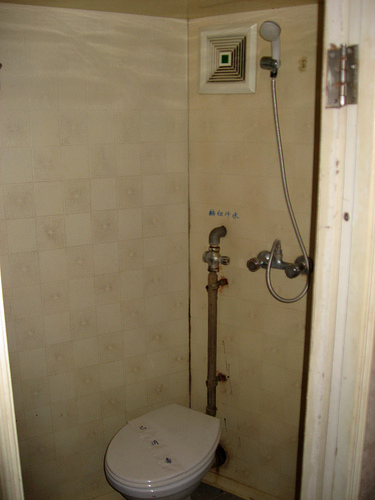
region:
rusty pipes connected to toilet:
[190, 204, 239, 444]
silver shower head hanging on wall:
[257, 20, 321, 306]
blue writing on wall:
[195, 203, 250, 224]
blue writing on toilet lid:
[125, 416, 189, 481]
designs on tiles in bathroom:
[7, 251, 96, 274]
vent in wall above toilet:
[190, 26, 262, 90]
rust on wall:
[211, 446, 247, 481]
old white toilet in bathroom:
[106, 406, 229, 494]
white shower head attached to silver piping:
[255, 17, 297, 75]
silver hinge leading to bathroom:
[320, 39, 363, 119]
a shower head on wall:
[206, 8, 373, 222]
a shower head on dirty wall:
[235, 2, 323, 259]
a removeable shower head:
[213, 5, 315, 183]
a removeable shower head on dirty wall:
[235, 9, 334, 251]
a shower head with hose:
[228, 7, 316, 307]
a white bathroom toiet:
[86, 350, 238, 493]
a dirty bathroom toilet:
[97, 361, 246, 495]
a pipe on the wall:
[166, 211, 243, 477]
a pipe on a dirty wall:
[179, 221, 257, 477]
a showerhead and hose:
[204, 11, 326, 346]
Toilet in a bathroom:
[100, 398, 221, 498]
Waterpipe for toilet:
[204, 271, 221, 417]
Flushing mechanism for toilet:
[198, 246, 231, 271]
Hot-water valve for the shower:
[245, 252, 263, 273]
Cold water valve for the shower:
[285, 257, 312, 278]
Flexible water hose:
[268, 103, 302, 235]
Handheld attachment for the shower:
[260, 19, 282, 67]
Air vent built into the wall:
[195, 23, 259, 100]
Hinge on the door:
[324, 38, 362, 111]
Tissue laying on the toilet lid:
[125, 411, 185, 479]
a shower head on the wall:
[202, 8, 362, 311]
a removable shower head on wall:
[235, 16, 337, 313]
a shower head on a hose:
[217, 7, 342, 307]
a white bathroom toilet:
[69, 340, 262, 498]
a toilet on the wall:
[99, 366, 269, 498]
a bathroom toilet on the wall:
[78, 357, 245, 495]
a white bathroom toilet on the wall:
[84, 334, 254, 496]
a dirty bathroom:
[33, 343, 313, 498]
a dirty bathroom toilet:
[49, 326, 285, 473]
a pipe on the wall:
[176, 224, 227, 420]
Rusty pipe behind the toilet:
[162, 214, 236, 432]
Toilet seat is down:
[124, 430, 223, 488]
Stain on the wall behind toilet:
[212, 440, 231, 475]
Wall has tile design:
[17, 217, 187, 383]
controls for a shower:
[221, 206, 336, 327]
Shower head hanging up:
[252, 11, 291, 92]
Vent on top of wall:
[188, 23, 265, 103]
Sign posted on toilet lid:
[130, 415, 180, 473]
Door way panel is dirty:
[299, 259, 361, 449]